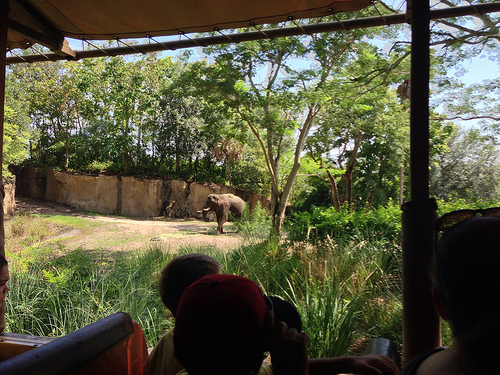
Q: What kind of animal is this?
A: Elephant.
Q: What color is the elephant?
A: Grey.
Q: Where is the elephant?
A: Enclosure.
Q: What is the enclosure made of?
A: Stone wall.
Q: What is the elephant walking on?
A: Dirt ground.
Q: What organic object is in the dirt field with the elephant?
A: Trees.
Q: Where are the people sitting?
A: Open vehicle.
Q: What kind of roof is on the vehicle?
A: Cloth roof.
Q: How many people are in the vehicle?
A: Three.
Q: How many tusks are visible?
A: One.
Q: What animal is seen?
A: Elephant.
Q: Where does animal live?
A: In zoo.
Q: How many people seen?
A: 4.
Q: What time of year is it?
A: Summer.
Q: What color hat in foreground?
A: Red.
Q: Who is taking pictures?
A: Person in red hat.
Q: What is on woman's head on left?
A: Sunglasses.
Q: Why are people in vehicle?
A: On a tour.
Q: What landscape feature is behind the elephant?
A: A small cliff face.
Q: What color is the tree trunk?
A: Brown.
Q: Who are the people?
A: Visitors to the zoo.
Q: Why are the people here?
A: They're on a safari.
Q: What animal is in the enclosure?
A: An elephant.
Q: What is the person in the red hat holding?
A: A camera.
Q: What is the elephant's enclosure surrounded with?
A: Trees.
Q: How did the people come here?
A: Riding in a vehicle.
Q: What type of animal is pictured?
A: An elephant.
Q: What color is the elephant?
A: Brown.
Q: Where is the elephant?
A: At a zoo.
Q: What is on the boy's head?
A: A cap.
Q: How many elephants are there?
A: One.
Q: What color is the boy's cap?
A: Red.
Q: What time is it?
A: Daytime.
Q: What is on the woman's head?
A: Sunglasses.